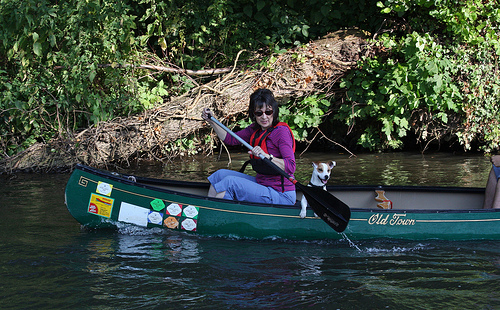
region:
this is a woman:
[153, 62, 303, 205]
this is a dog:
[297, 148, 355, 218]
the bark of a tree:
[37, 100, 134, 171]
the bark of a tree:
[120, 69, 242, 161]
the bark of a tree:
[254, 20, 372, 94]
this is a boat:
[61, 148, 498, 293]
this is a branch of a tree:
[57, 30, 151, 119]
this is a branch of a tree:
[340, 46, 450, 136]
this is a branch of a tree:
[35, 45, 127, 127]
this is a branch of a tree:
[168, 10, 249, 67]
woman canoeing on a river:
[0, 87, 499, 309]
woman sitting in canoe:
[200, 88, 295, 208]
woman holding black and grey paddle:
[205, 108, 352, 233]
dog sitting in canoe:
[299, 158, 337, 218]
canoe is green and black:
[63, 162, 498, 242]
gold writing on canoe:
[368, 213, 415, 228]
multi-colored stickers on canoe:
[86, 180, 199, 230]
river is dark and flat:
[0, 151, 498, 308]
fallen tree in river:
[0, 0, 499, 172]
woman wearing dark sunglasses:
[252, 107, 275, 116]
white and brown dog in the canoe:
[298, 157, 338, 217]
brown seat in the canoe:
[371, 187, 393, 212]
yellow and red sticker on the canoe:
[84, 188, 116, 220]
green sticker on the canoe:
[148, 195, 168, 211]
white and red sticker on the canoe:
[164, 200, 184, 217]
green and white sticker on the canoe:
[181, 200, 203, 220]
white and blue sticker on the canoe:
[147, 208, 165, 228]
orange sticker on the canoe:
[162, 213, 179, 230]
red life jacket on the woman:
[246, 120, 298, 172]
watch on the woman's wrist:
[265, 150, 275, 165]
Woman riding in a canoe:
[65, 86, 499, 245]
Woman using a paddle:
[200, 84, 351, 232]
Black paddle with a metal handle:
[205, 113, 350, 234]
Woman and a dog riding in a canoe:
[65, 88, 483, 245]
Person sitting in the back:
[480, 143, 497, 213]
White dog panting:
[300, 159, 337, 221]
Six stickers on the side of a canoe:
[145, 195, 200, 234]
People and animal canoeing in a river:
[0, 83, 499, 308]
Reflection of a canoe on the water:
[80, 225, 331, 308]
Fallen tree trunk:
[3, 22, 373, 172]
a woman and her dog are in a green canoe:
[72, 91, 499, 260]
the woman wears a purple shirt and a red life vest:
[205, 82, 307, 216]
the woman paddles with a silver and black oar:
[206, 86, 356, 239]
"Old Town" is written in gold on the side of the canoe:
[361, 208, 426, 230]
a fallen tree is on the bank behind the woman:
[8, 26, 365, 195]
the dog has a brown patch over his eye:
[298, 152, 343, 229]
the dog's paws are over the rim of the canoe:
[298, 155, 341, 220]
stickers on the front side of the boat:
[73, 171, 208, 233]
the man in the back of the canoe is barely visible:
[473, 146, 498, 212]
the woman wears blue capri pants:
[209, 166, 304, 207]